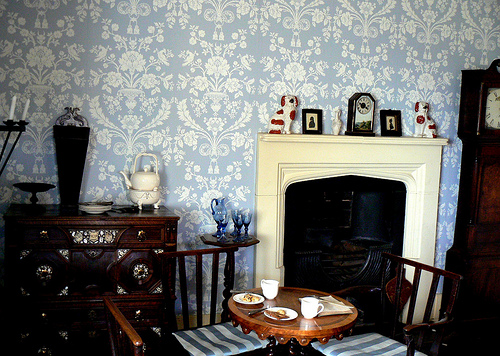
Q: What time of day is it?
A: Day time.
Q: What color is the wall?
A: Blue and white.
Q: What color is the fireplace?
A: White.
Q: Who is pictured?
A: No one.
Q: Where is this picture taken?
A: Dining room.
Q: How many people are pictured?
A: No one.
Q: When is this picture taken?
A: During day.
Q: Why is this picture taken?
A: Photography.